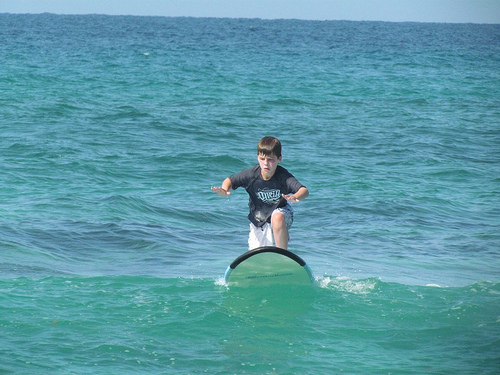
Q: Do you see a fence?
A: No, there are no fences.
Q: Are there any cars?
A: No, there are no cars.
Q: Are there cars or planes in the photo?
A: No, there are no cars or planes.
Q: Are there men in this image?
A: No, there are no men.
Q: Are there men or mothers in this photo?
A: No, there are no men or mothers.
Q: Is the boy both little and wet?
A: Yes, the boy is little and wet.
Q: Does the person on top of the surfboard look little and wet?
A: Yes, the boy is little and wet.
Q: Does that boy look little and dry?
A: No, the boy is little but wet.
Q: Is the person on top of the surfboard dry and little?
A: No, the boy is little but wet.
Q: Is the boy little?
A: Yes, the boy is little.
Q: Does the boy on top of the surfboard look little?
A: Yes, the boy is little.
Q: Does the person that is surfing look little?
A: Yes, the boy is little.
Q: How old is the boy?
A: The boy is little.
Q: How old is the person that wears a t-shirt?
A: The boy is little.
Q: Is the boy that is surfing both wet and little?
A: Yes, the boy is wet and little.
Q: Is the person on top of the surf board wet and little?
A: Yes, the boy is wet and little.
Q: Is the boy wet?
A: Yes, the boy is wet.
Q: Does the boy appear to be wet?
A: Yes, the boy is wet.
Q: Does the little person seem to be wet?
A: Yes, the boy is wet.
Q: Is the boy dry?
A: No, the boy is wet.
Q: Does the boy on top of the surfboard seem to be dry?
A: No, the boy is wet.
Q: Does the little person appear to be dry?
A: No, the boy is wet.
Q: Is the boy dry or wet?
A: The boy is wet.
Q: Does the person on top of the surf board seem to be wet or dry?
A: The boy is wet.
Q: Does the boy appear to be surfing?
A: Yes, the boy is surfing.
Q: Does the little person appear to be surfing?
A: Yes, the boy is surfing.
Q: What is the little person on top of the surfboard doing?
A: The boy is surfing.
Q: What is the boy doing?
A: The boy is surfing.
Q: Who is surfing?
A: The boy is surfing.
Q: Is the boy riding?
A: No, the boy is surfing.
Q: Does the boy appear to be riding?
A: No, the boy is surfing.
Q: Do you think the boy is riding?
A: No, the boy is surfing.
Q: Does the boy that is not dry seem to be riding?
A: No, the boy is surfing.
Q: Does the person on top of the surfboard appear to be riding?
A: No, the boy is surfing.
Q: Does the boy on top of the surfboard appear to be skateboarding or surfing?
A: The boy is surfing.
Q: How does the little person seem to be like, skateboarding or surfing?
A: The boy is surfing.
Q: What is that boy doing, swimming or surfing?
A: The boy is surfing.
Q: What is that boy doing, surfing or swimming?
A: The boy is surfing.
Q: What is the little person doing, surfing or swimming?
A: The boy is surfing.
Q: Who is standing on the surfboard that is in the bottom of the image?
A: The boy is standing on the surf board.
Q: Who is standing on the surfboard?
A: The boy is standing on the surf board.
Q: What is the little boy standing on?
A: The boy is standing on the surfboard.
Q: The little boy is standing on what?
A: The boy is standing on the surfboard.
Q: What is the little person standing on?
A: The boy is standing on the surfboard.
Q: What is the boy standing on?
A: The boy is standing on the surfboard.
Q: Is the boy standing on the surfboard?
A: Yes, the boy is standing on the surfboard.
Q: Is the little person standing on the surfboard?
A: Yes, the boy is standing on the surfboard.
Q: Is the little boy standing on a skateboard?
A: No, the boy is standing on the surfboard.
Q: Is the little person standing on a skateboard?
A: No, the boy is standing on the surfboard.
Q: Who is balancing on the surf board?
A: The boy is balancing on the surf board.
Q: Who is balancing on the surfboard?
A: The boy is balancing on the surf board.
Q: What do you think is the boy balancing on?
A: The boy is balancing on the surfboard.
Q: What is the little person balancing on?
A: The boy is balancing on the surfboard.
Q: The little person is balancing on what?
A: The boy is balancing on the surfboard.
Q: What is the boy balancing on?
A: The boy is balancing on the surfboard.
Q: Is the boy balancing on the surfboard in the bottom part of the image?
A: Yes, the boy is balancing on the surf board.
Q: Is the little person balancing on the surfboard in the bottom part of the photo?
A: Yes, the boy is balancing on the surf board.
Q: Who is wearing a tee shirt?
A: The boy is wearing a tee shirt.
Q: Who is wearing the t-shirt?
A: The boy is wearing a tee shirt.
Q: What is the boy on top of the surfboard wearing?
A: The boy is wearing a tee shirt.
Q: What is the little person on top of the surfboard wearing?
A: The boy is wearing a tee shirt.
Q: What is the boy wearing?
A: The boy is wearing a tee shirt.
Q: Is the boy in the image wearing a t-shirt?
A: Yes, the boy is wearing a t-shirt.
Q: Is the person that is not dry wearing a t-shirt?
A: Yes, the boy is wearing a t-shirt.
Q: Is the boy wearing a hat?
A: No, the boy is wearing a t-shirt.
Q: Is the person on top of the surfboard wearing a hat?
A: No, the boy is wearing a t-shirt.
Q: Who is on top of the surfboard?
A: The boy is on top of the surfboard.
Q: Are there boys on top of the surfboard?
A: Yes, there is a boy on top of the surfboard.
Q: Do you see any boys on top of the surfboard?
A: Yes, there is a boy on top of the surfboard.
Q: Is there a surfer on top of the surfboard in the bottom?
A: No, there is a boy on top of the surfboard.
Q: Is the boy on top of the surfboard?
A: Yes, the boy is on top of the surfboard.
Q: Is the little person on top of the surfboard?
A: Yes, the boy is on top of the surfboard.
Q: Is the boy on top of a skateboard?
A: No, the boy is on top of the surfboard.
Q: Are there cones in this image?
A: No, there are no cones.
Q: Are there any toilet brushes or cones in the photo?
A: No, there are no cones or toilet brushes.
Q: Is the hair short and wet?
A: Yes, the hair is short and wet.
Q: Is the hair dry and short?
A: No, the hair is short but wet.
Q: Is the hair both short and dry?
A: No, the hair is short but wet.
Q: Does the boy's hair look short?
A: Yes, the hair is short.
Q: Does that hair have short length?
A: Yes, the hair is short.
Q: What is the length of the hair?
A: The hair is short.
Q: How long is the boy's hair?
A: The hair is short.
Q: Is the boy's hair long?
A: No, the hair is short.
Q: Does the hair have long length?
A: No, the hair is short.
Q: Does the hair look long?
A: No, the hair is short.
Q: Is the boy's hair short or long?
A: The hair is short.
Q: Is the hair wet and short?
A: Yes, the hair is wet and short.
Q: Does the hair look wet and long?
A: No, the hair is wet but short.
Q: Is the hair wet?
A: Yes, the hair is wet.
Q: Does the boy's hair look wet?
A: Yes, the hair is wet.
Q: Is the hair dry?
A: No, the hair is wet.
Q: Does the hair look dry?
A: No, the hair is wet.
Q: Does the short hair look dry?
A: No, the hair is wet.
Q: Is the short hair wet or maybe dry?
A: The hair is wet.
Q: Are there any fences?
A: No, there are no fences.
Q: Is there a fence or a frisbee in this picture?
A: No, there are no fences or frisbees.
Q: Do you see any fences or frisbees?
A: No, there are no fences or frisbees.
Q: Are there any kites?
A: No, there are no kites.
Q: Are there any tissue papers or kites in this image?
A: No, there are no kites or tissue papers.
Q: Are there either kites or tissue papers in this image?
A: No, there are no kites or tissue papers.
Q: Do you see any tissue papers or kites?
A: No, there are no kites or tissue papers.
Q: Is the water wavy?
A: Yes, the water is wavy.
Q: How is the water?
A: The water is wavy.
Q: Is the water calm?
A: No, the water is wavy.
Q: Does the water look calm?
A: No, the water is wavy.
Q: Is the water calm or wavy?
A: The water is wavy.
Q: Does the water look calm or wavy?
A: The water is wavy.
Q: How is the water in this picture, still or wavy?
A: The water is wavy.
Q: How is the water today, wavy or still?
A: The water is wavy.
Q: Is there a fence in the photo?
A: No, there are no fences.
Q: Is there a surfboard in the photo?
A: Yes, there is a surfboard.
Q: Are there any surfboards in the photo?
A: Yes, there is a surfboard.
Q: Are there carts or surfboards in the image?
A: Yes, there is a surfboard.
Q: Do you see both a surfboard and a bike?
A: No, there is a surfboard but no bikes.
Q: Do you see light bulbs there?
A: No, there are no light bulbs.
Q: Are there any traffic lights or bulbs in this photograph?
A: No, there are no bulbs or traffic lights.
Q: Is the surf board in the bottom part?
A: Yes, the surf board is in the bottom of the image.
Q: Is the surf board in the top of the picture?
A: No, the surf board is in the bottom of the image.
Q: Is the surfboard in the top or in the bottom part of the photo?
A: The surfboard is in the bottom of the image.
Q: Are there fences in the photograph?
A: No, there are no fences.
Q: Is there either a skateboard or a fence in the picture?
A: No, there are no fences or skateboards.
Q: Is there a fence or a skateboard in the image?
A: No, there are no fences or skateboards.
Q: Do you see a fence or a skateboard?
A: No, there are no fences or skateboards.